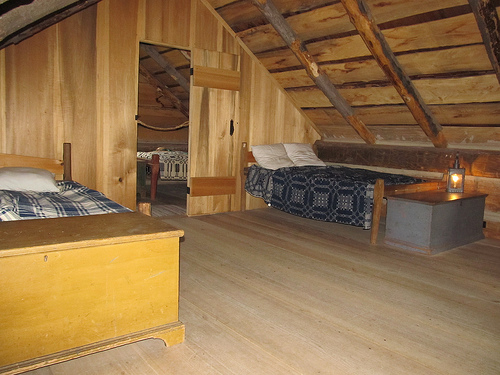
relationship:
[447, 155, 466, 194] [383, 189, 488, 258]
lantern sitting on a box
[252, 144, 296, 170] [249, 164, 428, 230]
pillow sitting on bed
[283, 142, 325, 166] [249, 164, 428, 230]
pillow sitting on bed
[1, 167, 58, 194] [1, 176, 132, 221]
pillow on top of a comforter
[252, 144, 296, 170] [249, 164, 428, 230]
pillow lying on a bed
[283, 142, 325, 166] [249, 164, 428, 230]
pillow lying on a bed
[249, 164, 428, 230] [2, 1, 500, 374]
bed sitting in a bedroom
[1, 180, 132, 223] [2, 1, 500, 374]
bed sitting in a bedroom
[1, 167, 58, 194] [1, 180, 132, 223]
pillow sitting on a bed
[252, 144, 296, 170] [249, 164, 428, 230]
pillow on bed